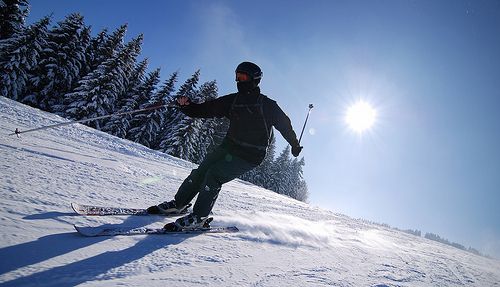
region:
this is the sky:
[306, 28, 454, 145]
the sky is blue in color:
[423, 52, 461, 107]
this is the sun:
[340, 91, 417, 157]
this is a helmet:
[233, 57, 267, 82]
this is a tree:
[31, 27, 68, 91]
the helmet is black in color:
[243, 61, 257, 73]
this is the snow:
[244, 205, 469, 283]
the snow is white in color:
[238, 240, 294, 276]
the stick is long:
[26, 108, 119, 133]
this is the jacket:
[233, 125, 263, 137]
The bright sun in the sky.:
[329, 90, 394, 137]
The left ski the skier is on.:
[53, 190, 195, 215]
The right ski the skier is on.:
[71, 215, 247, 247]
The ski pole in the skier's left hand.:
[7, 80, 193, 140]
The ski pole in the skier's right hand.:
[289, 95, 320, 164]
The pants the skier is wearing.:
[171, 141, 247, 219]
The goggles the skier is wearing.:
[229, 69, 261, 87]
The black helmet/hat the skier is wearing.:
[232, 61, 263, 73]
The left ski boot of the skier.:
[147, 185, 192, 212]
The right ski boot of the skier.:
[165, 206, 215, 229]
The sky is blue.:
[428, 17, 499, 111]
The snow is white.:
[250, 242, 398, 285]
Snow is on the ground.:
[245, 232, 382, 284]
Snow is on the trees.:
[3, 2, 189, 155]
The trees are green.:
[3, 2, 193, 147]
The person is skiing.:
[66, 46, 335, 260]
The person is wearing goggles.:
[208, 54, 271, 98]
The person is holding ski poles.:
[5, 83, 327, 185]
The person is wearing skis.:
[49, 161, 271, 253]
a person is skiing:
[21, 45, 330, 242]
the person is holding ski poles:
[17, 47, 347, 193]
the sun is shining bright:
[309, 76, 412, 185]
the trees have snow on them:
[15, 22, 165, 134]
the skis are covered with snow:
[46, 181, 166, 245]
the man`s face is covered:
[214, 54, 276, 93]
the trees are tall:
[5, 2, 170, 158]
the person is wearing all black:
[156, 47, 273, 211]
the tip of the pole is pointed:
[0, 122, 54, 149]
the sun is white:
[306, 79, 393, 204]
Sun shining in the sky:
[339, 95, 385, 137]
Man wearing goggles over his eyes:
[233, 71, 250, 83]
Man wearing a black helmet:
[235, 60, 265, 76]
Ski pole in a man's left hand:
[293, 95, 317, 160]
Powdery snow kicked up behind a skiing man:
[226, 210, 336, 241]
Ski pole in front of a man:
[7, 95, 189, 139]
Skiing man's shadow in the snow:
[1, 218, 163, 282]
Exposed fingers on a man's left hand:
[176, 92, 188, 106]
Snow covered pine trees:
[58, 20, 158, 135]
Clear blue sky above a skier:
[216, 10, 486, 72]